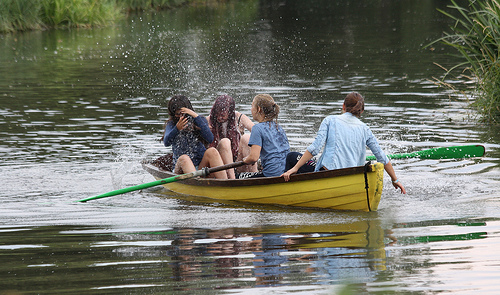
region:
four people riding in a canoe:
[139, 85, 409, 226]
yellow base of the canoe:
[317, 185, 366, 207]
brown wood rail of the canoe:
[313, 163, 360, 182]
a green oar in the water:
[66, 168, 216, 213]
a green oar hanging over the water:
[368, 134, 490, 176]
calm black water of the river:
[333, 25, 400, 78]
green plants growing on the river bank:
[11, 0, 121, 28]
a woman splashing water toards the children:
[290, 90, 420, 205]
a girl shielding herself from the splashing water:
[158, 87, 219, 191]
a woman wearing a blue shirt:
[303, 90, 391, 180]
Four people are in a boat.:
[141, 85, 411, 225]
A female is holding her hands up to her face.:
[157, 95, 213, 150]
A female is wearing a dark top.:
[160, 112, 216, 170]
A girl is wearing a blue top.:
[242, 95, 292, 180]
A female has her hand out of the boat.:
[363, 125, 408, 197]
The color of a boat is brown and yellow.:
[135, 145, 385, 216]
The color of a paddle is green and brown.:
[76, 155, 256, 210]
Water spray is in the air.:
[78, 12, 300, 183]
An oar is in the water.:
[76, 150, 262, 215]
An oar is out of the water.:
[360, 138, 489, 166]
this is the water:
[41, 62, 101, 96]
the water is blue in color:
[199, 246, 241, 291]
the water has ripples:
[29, 143, 61, 188]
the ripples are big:
[14, 109, 71, 181]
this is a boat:
[268, 177, 382, 219]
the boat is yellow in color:
[299, 180, 353, 204]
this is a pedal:
[71, 174, 184, 207]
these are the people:
[151, 84, 385, 171]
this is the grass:
[473, 30, 498, 88]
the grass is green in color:
[455, 20, 489, 62]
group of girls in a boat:
[140, 89, 406, 211]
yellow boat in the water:
[139, 153, 386, 207]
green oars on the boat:
[76, 135, 486, 207]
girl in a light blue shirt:
[284, 92, 399, 194]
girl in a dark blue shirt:
[159, 98, 220, 183]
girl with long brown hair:
[206, 96, 253, 156]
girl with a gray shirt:
[243, 93, 292, 176]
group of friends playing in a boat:
[140, 88, 412, 212]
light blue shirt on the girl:
[306, 113, 386, 170]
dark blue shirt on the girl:
[161, 111, 214, 164]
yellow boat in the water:
[0, 6, 496, 292]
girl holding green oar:
[72, 95, 287, 207]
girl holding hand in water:
[0, 5, 495, 290]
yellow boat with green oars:
[55, 140, 485, 205]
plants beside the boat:
[130, 0, 495, 210]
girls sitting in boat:
[140, 91, 400, 206]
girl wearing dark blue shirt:
[160, 91, 225, 176]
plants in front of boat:
[0, 0, 381, 215]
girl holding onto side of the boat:
[140, 90, 405, 210]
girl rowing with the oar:
[86, 90, 286, 205]